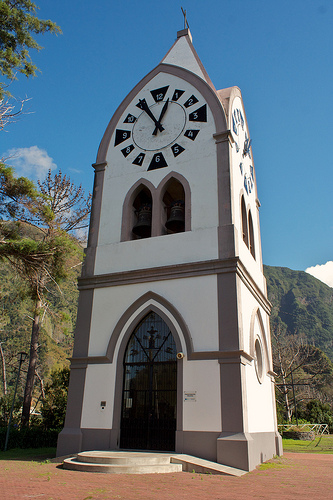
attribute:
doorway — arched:
[117, 303, 180, 454]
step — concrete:
[61, 455, 185, 475]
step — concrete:
[75, 448, 184, 464]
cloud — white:
[303, 258, 331, 285]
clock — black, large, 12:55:
[111, 83, 205, 171]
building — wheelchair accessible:
[63, 19, 278, 460]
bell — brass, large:
[129, 192, 150, 234]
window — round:
[247, 333, 273, 383]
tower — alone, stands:
[53, 27, 285, 475]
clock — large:
[115, 83, 209, 167]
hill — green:
[264, 262, 323, 352]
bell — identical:
[159, 199, 188, 232]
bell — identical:
[126, 201, 153, 237]